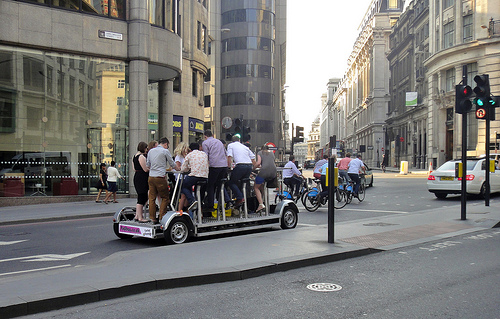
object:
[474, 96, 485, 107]
light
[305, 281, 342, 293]
manhole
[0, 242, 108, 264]
paint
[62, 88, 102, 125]
glass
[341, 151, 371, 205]
bunch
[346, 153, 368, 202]
bikes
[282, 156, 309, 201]
bikers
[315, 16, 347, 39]
sky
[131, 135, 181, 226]
people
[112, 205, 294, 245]
cart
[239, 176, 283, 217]
stools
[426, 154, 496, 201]
car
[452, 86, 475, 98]
lights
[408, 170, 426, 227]
intersection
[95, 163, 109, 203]
women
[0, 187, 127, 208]
sidewalk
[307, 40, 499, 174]
building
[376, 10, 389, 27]
back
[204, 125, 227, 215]
man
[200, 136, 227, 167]
shirt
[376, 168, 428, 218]
street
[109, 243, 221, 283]
passwalk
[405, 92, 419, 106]
sign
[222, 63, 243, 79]
window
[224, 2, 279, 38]
circular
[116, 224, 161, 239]
license plate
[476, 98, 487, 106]
green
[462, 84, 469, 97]
red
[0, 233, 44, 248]
arrow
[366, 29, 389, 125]
columns